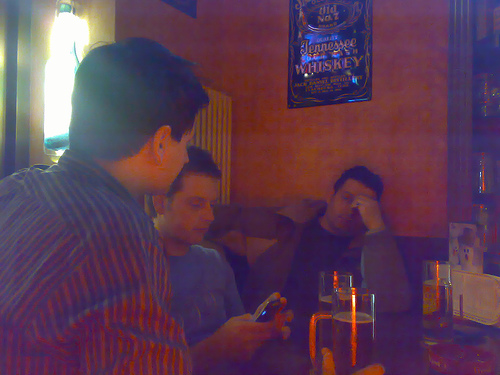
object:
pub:
[5, 11, 497, 346]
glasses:
[423, 259, 456, 348]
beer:
[331, 310, 373, 373]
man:
[273, 160, 404, 330]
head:
[323, 166, 383, 230]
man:
[159, 147, 274, 373]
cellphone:
[249, 294, 278, 325]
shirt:
[0, 161, 177, 370]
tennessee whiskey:
[288, 39, 367, 71]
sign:
[287, 0, 379, 109]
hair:
[74, 35, 203, 158]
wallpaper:
[222, 13, 438, 225]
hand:
[352, 194, 385, 230]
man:
[0, 36, 205, 374]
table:
[267, 251, 496, 375]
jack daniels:
[285, 38, 370, 81]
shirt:
[170, 239, 249, 342]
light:
[45, 12, 88, 140]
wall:
[231, 16, 445, 190]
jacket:
[258, 204, 395, 292]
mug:
[311, 286, 370, 373]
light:
[349, 288, 357, 367]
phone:
[251, 290, 292, 330]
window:
[21, 1, 99, 169]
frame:
[2, 7, 33, 168]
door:
[1, 13, 34, 165]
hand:
[316, 345, 378, 374]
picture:
[443, 222, 485, 270]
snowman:
[458, 225, 476, 269]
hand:
[207, 313, 262, 356]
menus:
[446, 266, 499, 323]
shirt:
[286, 226, 342, 283]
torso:
[268, 225, 354, 327]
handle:
[304, 313, 333, 373]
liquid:
[325, 312, 377, 372]